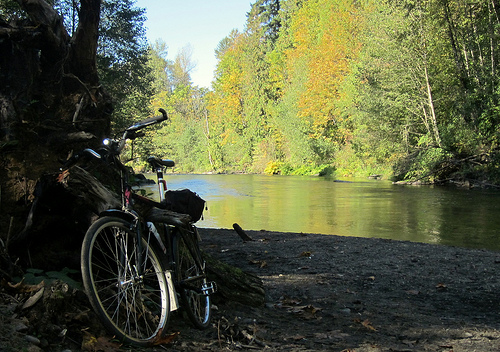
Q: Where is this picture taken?
A: The woods.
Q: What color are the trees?
A: Green.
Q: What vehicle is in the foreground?
A: A bike.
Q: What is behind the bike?
A: A lake.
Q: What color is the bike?
A: Black.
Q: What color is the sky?
A: Blue.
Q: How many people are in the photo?
A: None.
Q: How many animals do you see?
A: None.